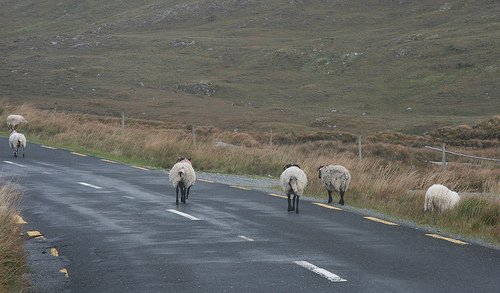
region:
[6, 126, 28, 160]
the black and white sheep walking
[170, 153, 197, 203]
the black and white sheep walking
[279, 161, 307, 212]
the black and white sheep walking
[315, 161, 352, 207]
the black and white sheep walking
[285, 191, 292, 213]
the black leg of the sheep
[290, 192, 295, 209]
the black leg of the sheep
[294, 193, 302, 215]
the black leg of the sheep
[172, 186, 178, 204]
the black leg of the sheep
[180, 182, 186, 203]
the black leg of the sheep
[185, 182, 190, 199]
the black leg of the sheep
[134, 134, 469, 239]
sheep walking freely through the road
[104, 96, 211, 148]
short fence around grassy hill area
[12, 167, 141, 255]
yellow and white stripes painted on road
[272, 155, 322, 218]
white sheep with long black legs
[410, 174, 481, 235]
white sheep grazing on the tall grass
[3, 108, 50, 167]
sheep walking on the paved road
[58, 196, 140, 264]
old pavement needs to be repaved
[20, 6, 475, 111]
hills covered in green grass and weeds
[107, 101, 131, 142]
post holding up short fence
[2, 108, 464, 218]
sheeps on the street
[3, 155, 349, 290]
white lines in the pavement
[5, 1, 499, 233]
large field with green grass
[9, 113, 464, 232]
flock of sheep in the street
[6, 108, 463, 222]
black thin legs of sheeps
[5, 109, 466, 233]
white wooly sheeps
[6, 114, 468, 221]
two sheeps on the side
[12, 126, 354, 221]
four sheeps inb the middle of the street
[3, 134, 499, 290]
pavement highway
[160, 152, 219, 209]
the sheep on the road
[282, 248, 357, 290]
white line on the road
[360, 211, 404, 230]
the yellow line on the road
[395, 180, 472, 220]
the sheep in the grass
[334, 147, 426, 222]
the grass is tall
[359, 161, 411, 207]
the grass is dry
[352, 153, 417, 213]
tall dry grass beside the road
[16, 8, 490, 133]
grass on the hillside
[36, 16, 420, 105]
rocks on the hillside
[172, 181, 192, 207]
sheep with black legs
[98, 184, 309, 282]
White lines in the street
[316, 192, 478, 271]
Yellow lines on the edge of road.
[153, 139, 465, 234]
Sheep in the road.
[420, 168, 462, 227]
Sheep eating grass.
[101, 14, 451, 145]
The grass on the hill.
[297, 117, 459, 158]
Bushes on the hill.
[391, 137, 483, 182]
A gate road on the grass.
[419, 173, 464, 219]
The sheep head is hidden.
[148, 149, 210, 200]
The sheep is white.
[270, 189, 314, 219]
The sheep has black legs.